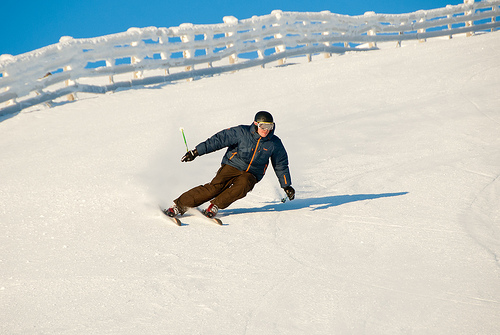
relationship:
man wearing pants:
[153, 107, 300, 226] [167, 165, 261, 217]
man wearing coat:
[153, 107, 300, 226] [190, 124, 302, 189]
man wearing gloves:
[153, 107, 300, 226] [176, 147, 202, 165]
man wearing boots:
[153, 107, 300, 226] [163, 202, 221, 218]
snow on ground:
[327, 68, 448, 180] [2, 39, 494, 334]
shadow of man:
[204, 184, 415, 226] [153, 107, 300, 226]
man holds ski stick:
[153, 107, 300, 226] [172, 112, 205, 162]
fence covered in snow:
[3, 4, 498, 120] [327, 68, 448, 180]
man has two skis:
[153, 107, 300, 226] [157, 199, 225, 234]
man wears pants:
[153, 107, 300, 226] [167, 165, 261, 217]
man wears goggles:
[153, 107, 300, 226] [256, 120, 274, 132]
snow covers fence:
[327, 68, 448, 180] [3, 4, 498, 120]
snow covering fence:
[327, 68, 448, 180] [3, 4, 498, 120]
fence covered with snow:
[3, 4, 498, 120] [327, 68, 448, 180]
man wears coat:
[153, 107, 300, 226] [190, 124, 302, 189]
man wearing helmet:
[153, 107, 300, 226] [249, 112, 278, 124]